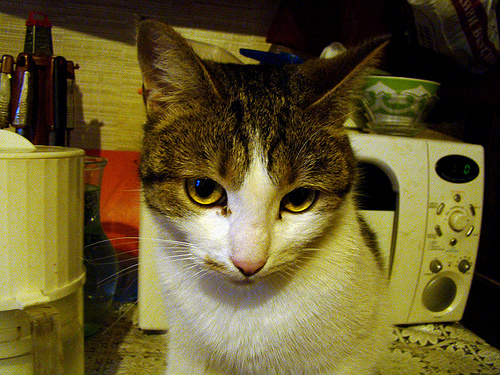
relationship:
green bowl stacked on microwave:
[352, 74, 441, 134] [139, 115, 486, 332]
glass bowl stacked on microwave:
[355, 73, 441, 136] [139, 115, 486, 332]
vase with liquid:
[80, 159, 130, 347] [80, 182, 119, 337]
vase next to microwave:
[80, 159, 130, 347] [337, 130, 482, 344]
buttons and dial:
[426, 195, 473, 281] [447, 209, 473, 235]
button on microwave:
[421, 273, 458, 314] [341, 117, 485, 328]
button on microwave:
[421, 273, 458, 314] [138, 199, 172, 331]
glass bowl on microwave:
[355, 89, 435, 136] [139, 115, 486, 332]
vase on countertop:
[72, 154, 119, 362] [33, 296, 499, 373]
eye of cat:
[182, 177, 226, 207] [134, 18, 393, 373]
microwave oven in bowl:
[135, 124, 483, 334] [353, 75, 440, 132]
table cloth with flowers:
[416, 310, 444, 351] [382, 319, 460, 372]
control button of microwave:
[409, 143, 483, 323] [170, 101, 498, 372]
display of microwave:
[428, 142, 495, 189] [133, 132, 483, 331]